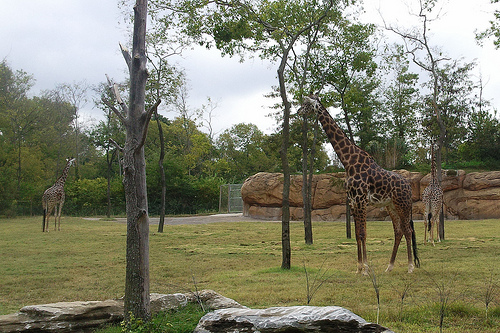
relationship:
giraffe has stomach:
[290, 93, 420, 277] [364, 189, 394, 210]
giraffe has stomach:
[420, 137, 444, 245] [431, 202, 442, 215]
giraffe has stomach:
[39, 157, 77, 232] [51, 200, 61, 210]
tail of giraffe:
[408, 209, 423, 269] [290, 93, 420, 277]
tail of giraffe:
[425, 197, 433, 233] [420, 137, 444, 245]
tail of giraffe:
[42, 198, 47, 233] [39, 157, 77, 232]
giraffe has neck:
[290, 93, 420, 277] [315, 106, 356, 168]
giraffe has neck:
[420, 137, 444, 245] [429, 150, 435, 178]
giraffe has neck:
[39, 157, 77, 232] [57, 164, 72, 187]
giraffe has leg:
[290, 93, 420, 277] [359, 201, 369, 273]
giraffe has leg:
[290, 93, 420, 277] [352, 211, 362, 274]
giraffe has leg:
[39, 157, 77, 232] [57, 204, 64, 234]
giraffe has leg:
[39, 157, 77, 232] [51, 203, 59, 232]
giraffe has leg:
[290, 93, 420, 277] [381, 208, 403, 277]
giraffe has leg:
[290, 93, 420, 277] [395, 188, 416, 275]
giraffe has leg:
[420, 137, 444, 245] [428, 200, 441, 247]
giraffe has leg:
[420, 137, 444, 245] [420, 196, 431, 247]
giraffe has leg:
[39, 157, 77, 232] [43, 201, 53, 233]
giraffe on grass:
[290, 93, 420, 277] [0, 215, 499, 331]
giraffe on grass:
[420, 137, 444, 245] [0, 215, 499, 331]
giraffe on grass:
[39, 157, 77, 232] [0, 215, 499, 331]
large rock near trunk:
[0, 300, 127, 333] [106, 1, 162, 324]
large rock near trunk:
[192, 305, 386, 332] [106, 1, 162, 324]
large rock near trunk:
[145, 288, 245, 310] [106, 1, 162, 324]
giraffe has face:
[290, 93, 420, 277] [295, 91, 322, 118]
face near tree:
[295, 91, 322, 118] [143, 0, 351, 274]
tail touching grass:
[408, 209, 423, 269] [0, 215, 499, 331]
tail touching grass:
[425, 197, 433, 233] [0, 215, 499, 331]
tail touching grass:
[42, 198, 47, 233] [0, 215, 499, 331]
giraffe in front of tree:
[290, 93, 420, 277] [379, 0, 461, 241]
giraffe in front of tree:
[420, 137, 444, 245] [379, 0, 461, 241]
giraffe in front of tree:
[39, 157, 77, 232] [40, 75, 95, 218]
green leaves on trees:
[163, 139, 223, 203] [2, 55, 498, 240]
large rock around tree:
[192, 305, 386, 332] [125, 0, 159, 324]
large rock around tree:
[145, 288, 245, 310] [125, 0, 159, 324]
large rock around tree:
[0, 297, 127, 332] [125, 0, 159, 324]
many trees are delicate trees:
[8, 37, 490, 282] [98, 2, 473, 277]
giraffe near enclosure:
[37, 157, 77, 229] [120, 184, 250, 225]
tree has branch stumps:
[110, 4, 181, 323] [112, 39, 169, 171]